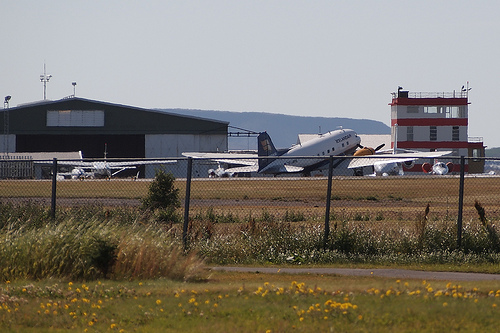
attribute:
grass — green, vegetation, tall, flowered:
[2, 220, 495, 332]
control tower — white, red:
[387, 82, 477, 175]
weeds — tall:
[197, 205, 417, 220]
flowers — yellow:
[235, 272, 332, 301]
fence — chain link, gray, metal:
[3, 154, 495, 251]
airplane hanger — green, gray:
[3, 94, 240, 179]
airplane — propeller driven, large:
[184, 126, 450, 175]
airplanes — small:
[58, 148, 246, 176]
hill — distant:
[170, 106, 394, 148]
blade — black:
[374, 144, 383, 152]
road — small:
[201, 260, 499, 285]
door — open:
[142, 134, 202, 174]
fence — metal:
[388, 90, 474, 101]